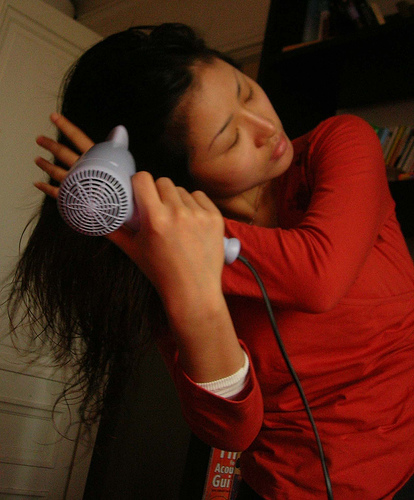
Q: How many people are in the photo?
A: One.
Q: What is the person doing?
A: Blowdrying hair.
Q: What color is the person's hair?
A: Black.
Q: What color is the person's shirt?
A: Red.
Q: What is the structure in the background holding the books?
A: Bookcase.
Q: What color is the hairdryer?
A: Lavender.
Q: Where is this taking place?
A: In a bathroom.